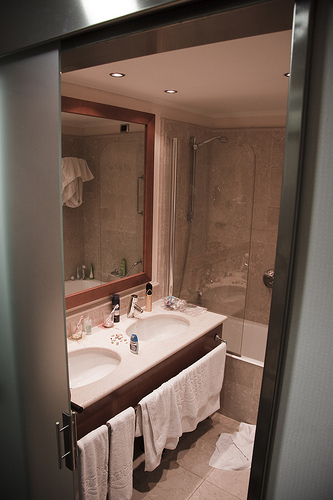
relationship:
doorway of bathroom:
[82, 118, 264, 499] [21, 35, 323, 490]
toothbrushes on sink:
[170, 269, 178, 309] [126, 318, 210, 343]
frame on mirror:
[141, 116, 157, 284] [69, 103, 158, 295]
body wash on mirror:
[109, 253, 133, 276] [69, 103, 158, 295]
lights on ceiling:
[111, 72, 193, 109] [87, 2, 274, 110]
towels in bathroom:
[83, 389, 180, 466] [21, 35, 323, 490]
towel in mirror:
[63, 162, 92, 202] [69, 103, 158, 295]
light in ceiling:
[105, 70, 141, 86] [87, 2, 274, 110]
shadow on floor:
[139, 426, 227, 488] [148, 406, 274, 487]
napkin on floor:
[200, 430, 231, 473] [148, 406, 274, 487]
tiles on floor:
[159, 446, 227, 497] [148, 406, 274, 487]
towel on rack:
[102, 414, 147, 496] [78, 407, 153, 432]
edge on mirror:
[59, 94, 164, 123] [69, 103, 158, 295]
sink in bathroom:
[126, 318, 210, 343] [21, 35, 323, 490]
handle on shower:
[258, 266, 280, 295] [174, 136, 277, 356]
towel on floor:
[63, 162, 92, 202] [148, 406, 274, 487]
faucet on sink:
[99, 300, 145, 316] [126, 318, 210, 343]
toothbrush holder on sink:
[70, 318, 86, 339] [126, 318, 210, 343]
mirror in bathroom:
[69, 103, 158, 295] [21, 35, 323, 490]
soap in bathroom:
[174, 295, 190, 312] [21, 35, 323, 490]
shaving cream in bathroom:
[108, 286, 120, 320] [21, 35, 323, 490]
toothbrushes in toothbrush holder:
[170, 269, 178, 309] [70, 318, 86, 339]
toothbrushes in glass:
[76, 312, 88, 329] [95, 306, 117, 329]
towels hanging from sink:
[83, 389, 180, 466] [126, 318, 210, 343]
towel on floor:
[210, 421, 286, 485] [148, 406, 274, 487]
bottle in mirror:
[109, 253, 133, 276] [69, 103, 158, 295]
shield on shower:
[158, 107, 314, 306] [174, 136, 277, 356]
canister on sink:
[102, 286, 126, 324] [126, 318, 210, 343]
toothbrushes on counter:
[170, 269, 178, 309] [82, 319, 191, 379]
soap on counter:
[174, 295, 190, 312] [82, 319, 191, 379]